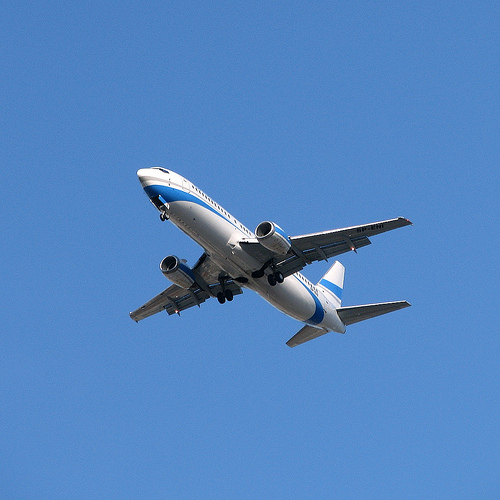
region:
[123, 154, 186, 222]
cockpit of a plane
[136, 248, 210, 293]
turbines of a plane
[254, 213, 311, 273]
turbines of a plane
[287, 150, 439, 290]
wing of a plane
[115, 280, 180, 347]
wing of a plane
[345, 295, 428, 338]
wing of a plane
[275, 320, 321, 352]
wing of a plane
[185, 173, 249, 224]
windows of a plane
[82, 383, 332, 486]
a clear blue sky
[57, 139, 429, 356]
plane in the air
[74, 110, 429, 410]
this is a plane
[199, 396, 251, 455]
the sky is very clear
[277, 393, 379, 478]
the sky is very clear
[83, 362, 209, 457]
the sky is very clear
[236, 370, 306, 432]
the sky is very clear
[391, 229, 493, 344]
the sky is very clear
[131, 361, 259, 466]
the sky is very clear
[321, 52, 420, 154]
the sky is very clear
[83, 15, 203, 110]
the sky is very clear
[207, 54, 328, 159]
the sky is very clear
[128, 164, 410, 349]
the airplane in the clear blue sky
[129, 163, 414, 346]
the airplane in mid air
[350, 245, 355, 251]
the light under the airplane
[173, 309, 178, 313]
the light under the airplane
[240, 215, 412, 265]
the wing on the airplane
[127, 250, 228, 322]
the wing on the airplane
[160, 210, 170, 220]
the wheels under the front of the airplane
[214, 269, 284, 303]
the wheels under the middle of the airplane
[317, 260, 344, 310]
the tail on the airplane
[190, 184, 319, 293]
the passenger windows on the side of the plane